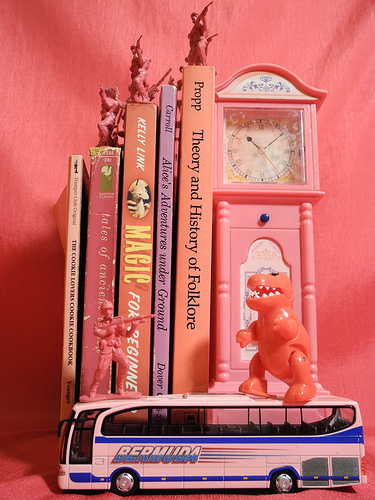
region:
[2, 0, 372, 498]
a bright pink background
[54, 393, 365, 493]
a toy tour bus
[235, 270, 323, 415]
a pink toy Tyrannosaurus Rex on the roof of the bus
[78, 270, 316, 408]
pink toy soldier with gum pointed in the direction of dinosaur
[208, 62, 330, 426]
a pink toy grandfather clock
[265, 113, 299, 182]
scratch on face of clock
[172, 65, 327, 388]
book leaning towards clock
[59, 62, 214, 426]
books lined up according to height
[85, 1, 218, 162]
pink soldier figurines on top of books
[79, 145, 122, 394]
a book that's cover is worn and scuffed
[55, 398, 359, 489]
White and blue color Toy Bus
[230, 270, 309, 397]
Orange color toy dinosaur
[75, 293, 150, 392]
Toy solider holding gun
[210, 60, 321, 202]
Pink wall Clock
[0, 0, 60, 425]
Pink wall at background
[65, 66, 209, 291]
Vertical Stacked books kept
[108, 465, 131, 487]
Front wheels of bus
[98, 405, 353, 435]
Transperent Windows of bus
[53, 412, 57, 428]
rear view mirror of bus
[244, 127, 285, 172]
Visible hands of clock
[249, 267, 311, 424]
Orange dinosaur standing on bus.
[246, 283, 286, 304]
Dinosaur has white teeth.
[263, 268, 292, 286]
Dinosaur has black eye.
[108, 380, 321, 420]
Top of bus is white.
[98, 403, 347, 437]
Windows a long side of bus.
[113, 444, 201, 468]
Writing on side of bus.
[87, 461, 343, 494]
Blue line on side of bus.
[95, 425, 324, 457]
Blue line under windows on side of bus.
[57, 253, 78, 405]
Cook book behind bus.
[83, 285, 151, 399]
Pink toy soldier on top of bus.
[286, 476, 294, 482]
part of a wheel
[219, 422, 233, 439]
part of a window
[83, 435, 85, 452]
part of a door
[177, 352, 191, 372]
part of a book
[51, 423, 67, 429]
part of a mirror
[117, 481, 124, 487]
part of a wheel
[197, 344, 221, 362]
part of a book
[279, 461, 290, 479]
edge of a wheel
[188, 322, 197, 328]
side of a book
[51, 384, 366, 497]
White toy passenger bus with blue stripes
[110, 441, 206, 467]
Bold letters on the side of the bus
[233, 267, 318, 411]
Orange dinasour on top of the bus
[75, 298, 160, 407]
Toy soldier on top of the bus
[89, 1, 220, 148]
Group of toy soldiers on top of the books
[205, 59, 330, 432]
Pink grandfather clock next to the books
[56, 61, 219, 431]
Group of books next to the clock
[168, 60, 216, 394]
Tallest orange book next to the clock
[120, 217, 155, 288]
Yellow lettering that says magic on the book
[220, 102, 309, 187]
Clockface in the pink grandfather clock